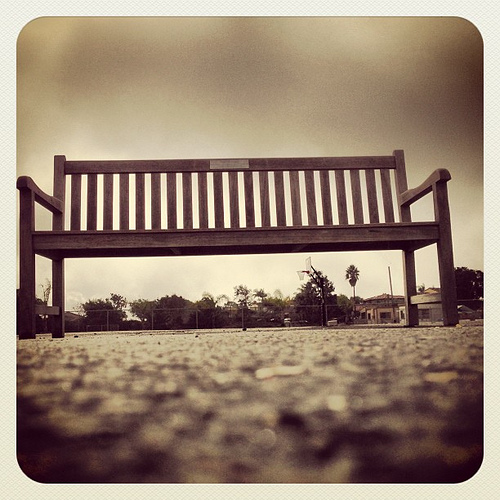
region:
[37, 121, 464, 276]
The bench is sitting in the park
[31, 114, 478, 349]
The bench is brown.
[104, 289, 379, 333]
Trees are in the background.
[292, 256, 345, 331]
A basketball hoop is in the park.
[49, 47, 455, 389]
The photo is taken in black and white.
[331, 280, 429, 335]
Houses are in the background.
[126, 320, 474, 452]
The ground has gravel and dirt.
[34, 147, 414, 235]
The bench is made of wood.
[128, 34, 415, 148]
The sky is dark and cloudy.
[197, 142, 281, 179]
A label is on the back of the bench.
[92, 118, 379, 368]
A bench is visible.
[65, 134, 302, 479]
A bench is visible.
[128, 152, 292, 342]
A bench is visible.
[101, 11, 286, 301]
A bench is visible.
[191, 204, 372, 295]
A bench is visible.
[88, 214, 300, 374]
A bench is visible.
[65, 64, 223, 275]
A bench is visible.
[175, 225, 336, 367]
A bench is visible.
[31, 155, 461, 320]
the bench is brown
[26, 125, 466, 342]
the bench is on ground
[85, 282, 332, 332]
the trees in distance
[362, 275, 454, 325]
structures in the background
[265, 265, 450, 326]
structures behind the court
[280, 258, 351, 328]
basketball goal on court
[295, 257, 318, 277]
the goal is white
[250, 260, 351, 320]
goal is behind fence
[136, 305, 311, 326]
the fence is metal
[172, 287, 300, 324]
trees are behind fence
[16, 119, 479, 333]
a wooden bench on gravel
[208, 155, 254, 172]
a metal plate on a wooden bench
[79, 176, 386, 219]
slats in the back of a wooden bench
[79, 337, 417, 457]
a close up of gravel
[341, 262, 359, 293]
a tall palm tree to the right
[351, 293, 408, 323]
a brown adobe building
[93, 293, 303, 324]
a line of trees behind a metal fence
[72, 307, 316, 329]
a long metal fence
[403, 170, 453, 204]
the right arm rest of a wooden bench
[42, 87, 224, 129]
a cloudy overcast sky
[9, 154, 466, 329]
a wooden bench.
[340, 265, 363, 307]
a tall leafy palm tree.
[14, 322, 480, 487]
a paved ground with a bench.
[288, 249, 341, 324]
a tall leafy tree tree.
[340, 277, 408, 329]
a house near a tall tree.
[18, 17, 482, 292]
a gray cloudy sky.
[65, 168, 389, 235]
support boards on a wooden bench.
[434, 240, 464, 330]
a wooden leg on a bench.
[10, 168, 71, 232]
an armrest on a bench.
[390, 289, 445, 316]
a building in the distance.